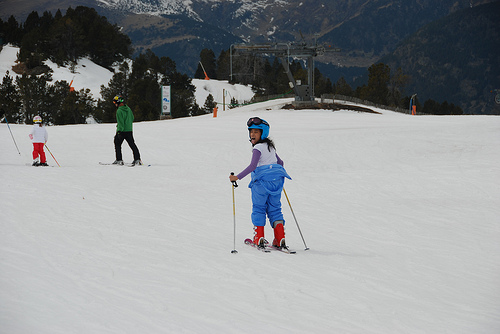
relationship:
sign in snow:
[160, 84, 171, 111] [1, 43, 498, 332]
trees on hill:
[19, 10, 128, 67] [3, 34, 173, 117]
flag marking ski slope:
[66, 77, 75, 94] [51, 77, 81, 121]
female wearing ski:
[234, 111, 291, 257] [240, 236, 272, 258]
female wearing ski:
[234, 111, 291, 257] [264, 235, 298, 251]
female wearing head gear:
[229, 117, 296, 255] [246, 115, 276, 145]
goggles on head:
[243, 115, 265, 125] [247, 114, 270, 140]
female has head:
[229, 117, 296, 255] [247, 114, 270, 140]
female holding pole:
[229, 117, 296, 255] [281, 184, 311, 250]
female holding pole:
[229, 117, 296, 255] [230, 176, 240, 254]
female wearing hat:
[229, 117, 296, 255] [246, 112, 271, 138]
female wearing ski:
[229, 117, 296, 255] [271, 239, 298, 255]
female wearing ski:
[229, 117, 296, 255] [243, 237, 274, 253]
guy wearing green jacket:
[112, 93, 141, 165] [112, 103, 134, 131]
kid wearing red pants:
[28, 115, 48, 166] [30, 143, 49, 166]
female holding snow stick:
[229, 117, 296, 255] [282, 189, 309, 251]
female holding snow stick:
[229, 117, 296, 255] [230, 171, 235, 253]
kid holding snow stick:
[26, 114, 47, 166] [42, 144, 62, 169]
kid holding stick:
[28, 115, 48, 166] [40, 140, 60, 168]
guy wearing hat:
[110, 92, 145, 165] [110, 90, 128, 106]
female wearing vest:
[229, 117, 296, 255] [256, 132, 280, 177]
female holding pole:
[229, 117, 296, 255] [230, 176, 238, 253]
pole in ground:
[211, 104, 217, 117] [0, 93, 499, 331]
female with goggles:
[229, 117, 296, 255] [246, 117, 269, 127]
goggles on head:
[246, 117, 269, 127] [242, 109, 272, 146]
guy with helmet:
[112, 93, 141, 165] [110, 90, 126, 108]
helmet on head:
[110, 90, 126, 108] [111, 92, 128, 112]